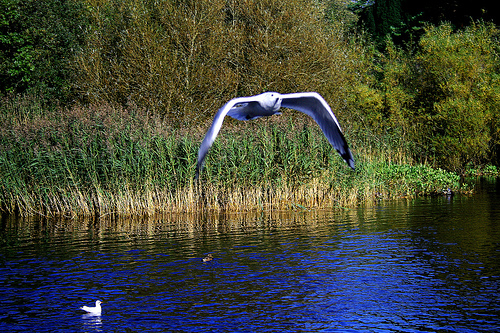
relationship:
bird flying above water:
[223, 87, 287, 122] [1, 185, 499, 332]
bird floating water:
[78, 298, 106, 316] [1, 185, 499, 332]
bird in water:
[78, 298, 106, 316] [146, 221, 381, 323]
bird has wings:
[194, 87, 358, 173] [189, 114, 356, 181]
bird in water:
[78, 300, 103, 317] [1, 185, 499, 332]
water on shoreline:
[1, 185, 499, 332] [0, 167, 499, 229]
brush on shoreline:
[0, 90, 460, 218] [0, 167, 499, 229]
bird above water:
[194, 87, 358, 173] [1, 185, 499, 332]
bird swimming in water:
[78, 298, 106, 316] [0, 197, 493, 331]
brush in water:
[0, 90, 460, 218] [1, 185, 499, 332]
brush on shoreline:
[0, 90, 490, 218] [3, 174, 498, 210]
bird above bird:
[194, 87, 358, 173] [78, 298, 106, 316]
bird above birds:
[194, 87, 358, 173] [198, 251, 220, 264]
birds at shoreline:
[71, 82, 476, 328] [0, 1, 499, 220]